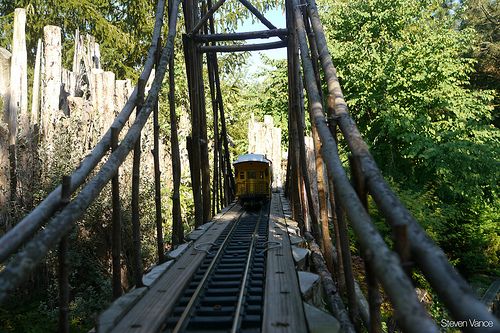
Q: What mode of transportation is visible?
A: Train.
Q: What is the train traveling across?
A: Bridge.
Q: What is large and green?
A: Trees.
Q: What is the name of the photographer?
A: Steven Vance.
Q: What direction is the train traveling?
A: Toward the camera.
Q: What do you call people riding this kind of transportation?
A: Passengers.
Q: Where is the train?
A: On the tracks.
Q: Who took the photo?
A: Steven Vance.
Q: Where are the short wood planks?
A: Under tracks.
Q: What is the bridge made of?
A: Wood.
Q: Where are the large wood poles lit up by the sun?
A: Left of bridge.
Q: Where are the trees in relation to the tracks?
A: Both sides.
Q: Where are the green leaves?
A: On trees.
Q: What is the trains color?
A: Yellow.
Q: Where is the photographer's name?
A: Bottom right.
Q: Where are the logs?
A: In the wall.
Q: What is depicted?
A: A train in the forest.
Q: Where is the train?
A: On the bridge.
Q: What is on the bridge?
A: A train.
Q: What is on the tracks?
A: A train.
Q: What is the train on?
A: A bridge.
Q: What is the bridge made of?
A: Wood.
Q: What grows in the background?
A: Trees.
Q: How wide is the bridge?
A: Narrow.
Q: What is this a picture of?
A: Train.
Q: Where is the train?
A: On a train track.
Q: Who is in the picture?
A: Nobody.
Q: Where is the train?
A: On the track.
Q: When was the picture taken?
A: During the day.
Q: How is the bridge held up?
A: By wood.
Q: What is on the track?
A: A train.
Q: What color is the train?
A: Yellow.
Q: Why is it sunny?
A: It is daytime.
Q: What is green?
A: The trees.